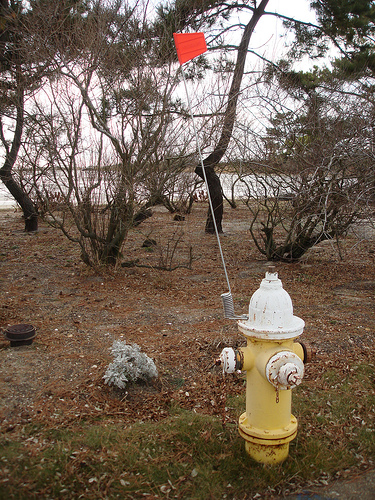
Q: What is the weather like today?
A: It is clear.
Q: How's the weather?
A: It is clear.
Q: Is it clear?
A: Yes, it is clear.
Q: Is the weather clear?
A: Yes, it is clear.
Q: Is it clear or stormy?
A: It is clear.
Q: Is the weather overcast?
A: No, it is clear.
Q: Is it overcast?
A: No, it is clear.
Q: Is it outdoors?
A: Yes, it is outdoors.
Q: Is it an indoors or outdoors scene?
A: It is outdoors.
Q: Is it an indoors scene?
A: No, it is outdoors.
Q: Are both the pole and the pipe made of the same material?
A: Yes, both the pole and the pipe are made of metal.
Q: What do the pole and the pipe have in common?
A: The material, both the pole and the pipe are metallic.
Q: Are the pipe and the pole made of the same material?
A: Yes, both the pipe and the pole are made of metal.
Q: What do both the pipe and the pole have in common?
A: The material, both the pipe and the pole are metallic.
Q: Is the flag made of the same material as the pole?
A: No, the flag is made of plastic and the pole is made of metal.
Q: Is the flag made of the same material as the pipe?
A: No, the flag is made of plastic and the pipe is made of metal.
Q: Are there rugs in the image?
A: No, there are no rugs.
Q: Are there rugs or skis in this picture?
A: No, there are no rugs or skis.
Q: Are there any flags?
A: Yes, there is a flag.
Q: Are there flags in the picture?
A: Yes, there is a flag.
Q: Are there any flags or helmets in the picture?
A: Yes, there is a flag.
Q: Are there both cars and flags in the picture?
A: No, there is a flag but no cars.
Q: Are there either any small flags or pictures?
A: Yes, there is a small flag.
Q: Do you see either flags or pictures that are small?
A: Yes, the flag is small.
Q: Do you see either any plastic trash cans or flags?
A: Yes, there is a plastic flag.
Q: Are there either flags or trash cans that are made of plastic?
A: Yes, the flag is made of plastic.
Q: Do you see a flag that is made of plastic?
A: Yes, there is a flag that is made of plastic.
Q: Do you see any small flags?
A: Yes, there is a small flag.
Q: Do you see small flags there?
A: Yes, there is a small flag.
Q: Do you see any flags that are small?
A: Yes, there is a flag that is small.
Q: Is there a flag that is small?
A: Yes, there is a flag that is small.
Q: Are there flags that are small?
A: Yes, there is a flag that is small.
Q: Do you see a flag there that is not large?
A: Yes, there is a small flag.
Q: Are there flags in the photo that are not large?
A: Yes, there is a small flag.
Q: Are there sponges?
A: No, there are no sponges.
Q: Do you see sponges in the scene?
A: No, there are no sponges.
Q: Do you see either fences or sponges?
A: No, there are no sponges or fences.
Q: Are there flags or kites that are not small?
A: No, there is a flag but it is small.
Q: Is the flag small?
A: Yes, the flag is small.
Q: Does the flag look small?
A: Yes, the flag is small.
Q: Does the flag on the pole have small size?
A: Yes, the flag is small.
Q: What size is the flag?
A: The flag is small.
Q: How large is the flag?
A: The flag is small.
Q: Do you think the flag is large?
A: No, the flag is small.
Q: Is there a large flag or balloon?
A: No, there is a flag but it is small.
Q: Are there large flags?
A: No, there is a flag but it is small.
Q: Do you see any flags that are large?
A: No, there is a flag but it is small.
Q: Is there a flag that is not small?
A: No, there is a flag but it is small.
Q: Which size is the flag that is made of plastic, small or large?
A: The flag is small.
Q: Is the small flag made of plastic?
A: Yes, the flag is made of plastic.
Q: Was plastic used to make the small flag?
A: Yes, the flag is made of plastic.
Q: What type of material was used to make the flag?
A: The flag is made of plastic.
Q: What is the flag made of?
A: The flag is made of plastic.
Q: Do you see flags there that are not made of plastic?
A: No, there is a flag but it is made of plastic.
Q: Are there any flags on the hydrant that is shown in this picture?
A: Yes, there is a flag on the hydrant.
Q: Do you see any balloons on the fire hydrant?
A: No, there is a flag on the fire hydrant.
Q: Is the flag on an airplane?
A: No, the flag is on the hydrant.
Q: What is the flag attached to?
A: The flag is attached to the hydrant.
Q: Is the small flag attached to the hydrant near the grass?
A: Yes, the flag is attached to the hydrant.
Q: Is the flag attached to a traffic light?
A: No, the flag is attached to the hydrant.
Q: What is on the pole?
A: The flag is on the pole.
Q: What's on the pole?
A: The flag is on the pole.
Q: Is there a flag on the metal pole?
A: Yes, there is a flag on the pole.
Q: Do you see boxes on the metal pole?
A: No, there is a flag on the pole.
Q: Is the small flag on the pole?
A: Yes, the flag is on the pole.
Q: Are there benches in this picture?
A: No, there are no benches.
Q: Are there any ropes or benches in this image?
A: No, there are no benches or ropes.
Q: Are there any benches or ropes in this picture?
A: No, there are no benches or ropes.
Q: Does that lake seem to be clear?
A: Yes, the lake is clear.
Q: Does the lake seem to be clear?
A: Yes, the lake is clear.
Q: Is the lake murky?
A: No, the lake is clear.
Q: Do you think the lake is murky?
A: No, the lake is clear.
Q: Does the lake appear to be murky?
A: No, the lake is clear.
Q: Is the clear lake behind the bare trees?
A: Yes, the lake is behind the trees.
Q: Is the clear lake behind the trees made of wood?
A: Yes, the lake is behind the trees.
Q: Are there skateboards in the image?
A: No, there are no skateboards.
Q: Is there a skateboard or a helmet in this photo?
A: No, there are no skateboards or helmets.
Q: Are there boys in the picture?
A: No, there are no boys.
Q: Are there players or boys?
A: No, there are no boys or players.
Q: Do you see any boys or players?
A: No, there are no boys or players.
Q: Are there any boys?
A: No, there are no boys.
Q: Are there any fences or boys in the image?
A: No, there are no boys or fences.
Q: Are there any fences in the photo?
A: No, there are no fences.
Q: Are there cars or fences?
A: No, there are no fences or cars.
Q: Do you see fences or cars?
A: No, there are no fences or cars.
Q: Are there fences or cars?
A: No, there are no fences or cars.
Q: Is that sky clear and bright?
A: Yes, the sky is clear and bright.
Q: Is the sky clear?
A: Yes, the sky is clear.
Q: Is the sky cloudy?
A: No, the sky is clear.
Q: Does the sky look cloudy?
A: No, the sky is clear.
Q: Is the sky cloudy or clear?
A: The sky is clear.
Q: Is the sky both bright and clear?
A: Yes, the sky is bright and clear.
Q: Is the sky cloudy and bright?
A: No, the sky is bright but clear.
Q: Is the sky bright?
A: Yes, the sky is bright.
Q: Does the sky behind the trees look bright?
A: Yes, the sky is bright.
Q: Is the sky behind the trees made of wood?
A: Yes, the sky is behind the trees.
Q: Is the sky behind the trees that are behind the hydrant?
A: Yes, the sky is behind the trees.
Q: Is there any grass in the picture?
A: Yes, there is grass.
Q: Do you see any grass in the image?
A: Yes, there is grass.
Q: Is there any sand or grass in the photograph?
A: Yes, there is grass.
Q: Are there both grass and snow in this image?
A: No, there is grass but no snow.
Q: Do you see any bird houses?
A: No, there are no bird houses.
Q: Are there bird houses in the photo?
A: No, there are no bird houses.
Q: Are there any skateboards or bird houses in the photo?
A: No, there are no bird houses or skateboards.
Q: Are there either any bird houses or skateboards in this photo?
A: No, there are no bird houses or skateboards.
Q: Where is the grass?
A: The grass is on the ground.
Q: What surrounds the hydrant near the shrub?
A: The grass surrounds the hydrant.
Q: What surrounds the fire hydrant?
A: The grass surrounds the hydrant.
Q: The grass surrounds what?
A: The grass surrounds the hydrant.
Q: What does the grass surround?
A: The grass surrounds the hydrant.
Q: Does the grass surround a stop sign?
A: No, the grass surrounds the fire hydrant.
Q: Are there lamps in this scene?
A: No, there are no lamps.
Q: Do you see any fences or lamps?
A: No, there are no lamps or fences.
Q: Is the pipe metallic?
A: Yes, the pipe is metallic.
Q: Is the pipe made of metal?
A: Yes, the pipe is made of metal.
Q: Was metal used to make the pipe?
A: Yes, the pipe is made of metal.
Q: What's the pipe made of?
A: The pipe is made of metal.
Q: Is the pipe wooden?
A: No, the pipe is metallic.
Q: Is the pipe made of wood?
A: No, the pipe is made of metal.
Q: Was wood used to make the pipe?
A: No, the pipe is made of metal.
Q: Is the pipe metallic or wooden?
A: The pipe is metallic.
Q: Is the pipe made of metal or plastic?
A: The pipe is made of metal.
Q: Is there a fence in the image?
A: No, there are no fences.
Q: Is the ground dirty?
A: Yes, the ground is dirty.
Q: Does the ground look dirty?
A: Yes, the ground is dirty.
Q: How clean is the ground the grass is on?
A: The ground is dirty.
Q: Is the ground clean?
A: No, the ground is dirty.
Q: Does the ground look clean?
A: No, the ground is dirty.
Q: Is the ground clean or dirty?
A: The ground is dirty.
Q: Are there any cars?
A: No, there are no cars.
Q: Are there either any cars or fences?
A: No, there are no cars or fences.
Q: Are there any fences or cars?
A: No, there are no cars or fences.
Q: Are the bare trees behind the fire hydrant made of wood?
A: Yes, the trees are made of wood.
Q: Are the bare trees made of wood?
A: Yes, the trees are made of wood.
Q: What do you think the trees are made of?
A: The trees are made of wood.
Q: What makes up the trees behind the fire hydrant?
A: The trees are made of wood.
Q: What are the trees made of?
A: The trees are made of wood.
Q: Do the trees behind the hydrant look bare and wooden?
A: Yes, the trees are bare and wooden.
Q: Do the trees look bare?
A: Yes, the trees are bare.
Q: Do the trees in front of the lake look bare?
A: Yes, the trees are bare.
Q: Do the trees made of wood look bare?
A: Yes, the trees are bare.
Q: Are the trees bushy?
A: No, the trees are bare.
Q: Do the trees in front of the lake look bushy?
A: No, the trees are bare.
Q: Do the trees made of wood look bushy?
A: No, the trees are bare.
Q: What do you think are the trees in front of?
A: The trees are in front of the lake.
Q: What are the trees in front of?
A: The trees are in front of the lake.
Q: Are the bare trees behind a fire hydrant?
A: Yes, the trees are behind a fire hydrant.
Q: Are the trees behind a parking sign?
A: No, the trees are behind a fire hydrant.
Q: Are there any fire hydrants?
A: Yes, there is a fire hydrant.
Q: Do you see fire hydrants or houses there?
A: Yes, there is a fire hydrant.